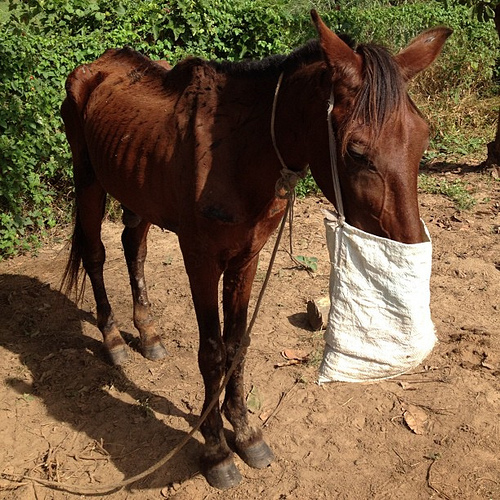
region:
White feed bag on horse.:
[268, 93, 477, 420]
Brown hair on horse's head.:
[347, 39, 429, 157]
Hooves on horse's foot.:
[187, 395, 265, 494]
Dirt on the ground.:
[317, 386, 427, 475]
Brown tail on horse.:
[37, 95, 119, 293]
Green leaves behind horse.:
[125, 7, 242, 72]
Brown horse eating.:
[60, 38, 470, 417]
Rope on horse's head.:
[25, 336, 207, 483]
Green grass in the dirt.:
[440, 171, 476, 220]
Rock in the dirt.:
[300, 277, 349, 342]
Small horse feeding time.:
[57, 39, 444, 484]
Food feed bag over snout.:
[321, 218, 453, 399]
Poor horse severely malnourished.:
[79, 39, 258, 230]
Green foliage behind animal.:
[7, 6, 499, 117]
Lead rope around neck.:
[113, 46, 299, 492]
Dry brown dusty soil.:
[263, 369, 498, 476]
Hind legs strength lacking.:
[69, 179, 194, 374]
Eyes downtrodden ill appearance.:
[334, 104, 436, 187]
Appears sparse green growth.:
[441, 82, 496, 251]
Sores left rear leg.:
[115, 233, 162, 320]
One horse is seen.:
[54, 66, 423, 464]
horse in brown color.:
[90, 112, 253, 178]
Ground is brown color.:
[321, 385, 432, 496]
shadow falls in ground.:
[8, 287, 179, 482]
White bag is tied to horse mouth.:
[325, 216, 447, 358]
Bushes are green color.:
[30, 26, 165, 52]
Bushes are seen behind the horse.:
[10, 32, 365, 82]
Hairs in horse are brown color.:
[260, 40, 362, 66]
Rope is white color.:
[273, 155, 294, 205]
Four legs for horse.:
[61, 210, 298, 476]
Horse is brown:
[33, 1, 468, 498]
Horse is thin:
[34, 8, 463, 495]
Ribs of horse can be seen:
[85, 95, 177, 195]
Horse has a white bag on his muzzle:
[46, 3, 457, 490]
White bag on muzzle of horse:
[301, 192, 452, 403]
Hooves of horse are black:
[170, 430, 288, 496]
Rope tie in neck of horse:
[196, 56, 297, 407]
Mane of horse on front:
[346, 32, 414, 152]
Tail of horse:
[38, 173, 109, 309]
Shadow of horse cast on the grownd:
[6, 273, 198, 487]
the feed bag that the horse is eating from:
[321, 213, 445, 379]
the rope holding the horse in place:
[4, 164, 266, 499]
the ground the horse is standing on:
[7, 215, 494, 499]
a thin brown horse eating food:
[56, 45, 492, 477]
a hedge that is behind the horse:
[1, 4, 496, 174]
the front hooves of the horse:
[197, 442, 269, 488]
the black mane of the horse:
[348, 41, 403, 131]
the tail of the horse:
[55, 241, 87, 310]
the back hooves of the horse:
[111, 335, 171, 368]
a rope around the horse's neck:
[251, 72, 294, 189]